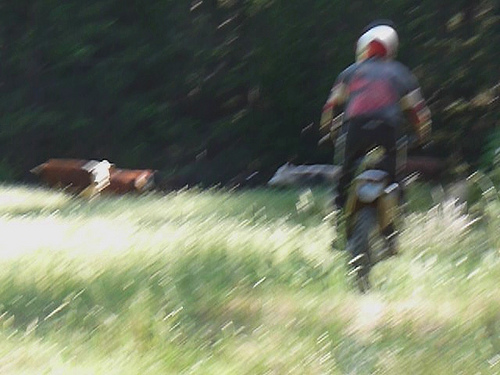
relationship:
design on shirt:
[347, 66, 399, 117] [327, 53, 414, 120]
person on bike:
[251, 31, 436, 297] [274, 97, 424, 273]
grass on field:
[1, 182, 498, 374] [1, 179, 496, 371]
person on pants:
[319, 25, 434, 293] [335, 120, 397, 207]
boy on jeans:
[321, 22, 431, 255] [334, 112, 402, 207]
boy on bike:
[321, 22, 431, 255] [348, 169, 387, 293]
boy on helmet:
[321, 22, 431, 255] [346, 18, 414, 60]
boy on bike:
[321, 22, 431, 255] [341, 166, 392, 292]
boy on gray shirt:
[321, 22, 431, 255] [337, 62, 414, 121]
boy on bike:
[325, 19, 432, 169] [348, 171, 396, 291]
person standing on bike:
[319, 25, 434, 293] [315, 134, 427, 324]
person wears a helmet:
[319, 25, 434, 293] [353, 21, 404, 56]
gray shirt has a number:
[337, 62, 414, 121] [349, 69, 390, 118]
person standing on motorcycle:
[319, 25, 434, 293] [325, 157, 412, 278]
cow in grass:
[103, 166, 163, 194] [1, 182, 498, 374]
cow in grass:
[30, 153, 116, 197] [1, 182, 498, 374]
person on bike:
[319, 25, 434, 293] [322, 106, 431, 293]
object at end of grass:
[28, 132, 159, 207] [1, 182, 498, 374]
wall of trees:
[30, 46, 264, 141] [10, 6, 497, 194]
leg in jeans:
[330, 119, 352, 235] [337, 96, 399, 219]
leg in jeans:
[379, 126, 396, 187] [337, 96, 399, 219]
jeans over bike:
[337, 96, 399, 219] [325, 100, 412, 282]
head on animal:
[265, 155, 310, 185] [256, 151, 390, 242]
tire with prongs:
[345, 205, 384, 292] [363, 240, 394, 285]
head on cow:
[77, 157, 112, 191] [67, 155, 112, 222]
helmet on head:
[352, 24, 399, 58] [341, 30, 415, 78]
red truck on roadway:
[30, 159, 158, 194] [403, 148, 467, 186]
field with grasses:
[59, 197, 394, 316] [104, 204, 372, 324]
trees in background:
[0, 2, 498, 177] [101, 50, 277, 163]